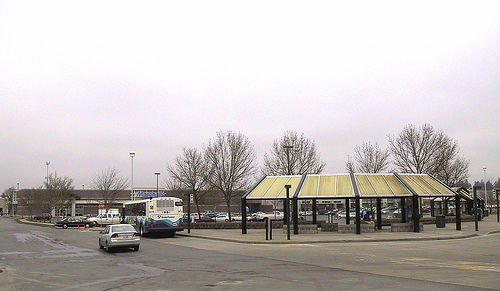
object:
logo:
[164, 211, 168, 214]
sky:
[0, 0, 499, 192]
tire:
[62, 224, 67, 229]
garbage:
[435, 215, 445, 228]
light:
[154, 172, 161, 197]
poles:
[15, 150, 192, 234]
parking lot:
[50, 186, 483, 224]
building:
[0, 187, 500, 217]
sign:
[190, 194, 194, 204]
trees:
[15, 124, 500, 224]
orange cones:
[77, 224, 86, 230]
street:
[0, 213, 500, 290]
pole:
[241, 198, 247, 234]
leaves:
[199, 130, 252, 192]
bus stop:
[241, 172, 500, 239]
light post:
[128, 151, 136, 201]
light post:
[151, 169, 163, 194]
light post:
[42, 160, 56, 197]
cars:
[54, 197, 184, 252]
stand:
[241, 172, 460, 201]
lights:
[151, 218, 183, 227]